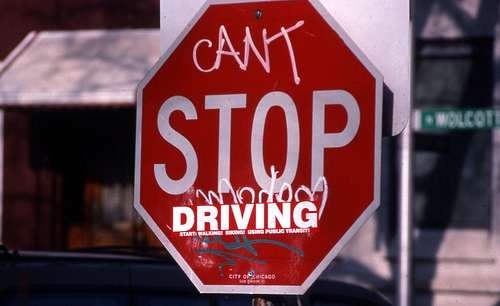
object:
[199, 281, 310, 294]
border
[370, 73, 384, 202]
border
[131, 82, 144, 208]
border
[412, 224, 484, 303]
structure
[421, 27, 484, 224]
shadow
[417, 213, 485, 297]
wall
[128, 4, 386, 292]
shape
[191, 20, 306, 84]
cant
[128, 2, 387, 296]
poster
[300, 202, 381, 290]
border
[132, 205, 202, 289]
border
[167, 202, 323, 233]
bumper sticker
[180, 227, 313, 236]
public transportation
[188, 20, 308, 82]
contraction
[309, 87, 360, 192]
p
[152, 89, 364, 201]
font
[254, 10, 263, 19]
bolt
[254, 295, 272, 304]
pole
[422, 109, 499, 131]
background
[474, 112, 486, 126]
letter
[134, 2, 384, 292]
signal board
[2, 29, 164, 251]
building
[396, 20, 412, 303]
pole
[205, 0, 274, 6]
border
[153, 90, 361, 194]
"stop"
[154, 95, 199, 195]
letters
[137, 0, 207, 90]
side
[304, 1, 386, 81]
side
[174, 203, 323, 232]
sticker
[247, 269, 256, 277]
screw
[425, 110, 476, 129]
lettering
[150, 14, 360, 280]
graffiti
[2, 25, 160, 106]
roof